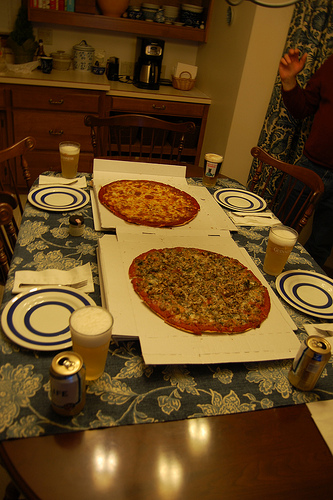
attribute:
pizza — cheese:
[93, 171, 208, 232]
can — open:
[37, 345, 98, 420]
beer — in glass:
[258, 223, 301, 278]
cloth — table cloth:
[133, 369, 210, 411]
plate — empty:
[215, 183, 273, 228]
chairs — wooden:
[4, 119, 330, 245]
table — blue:
[3, 138, 332, 419]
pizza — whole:
[129, 247, 271, 334]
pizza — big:
[125, 244, 275, 339]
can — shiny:
[49, 351, 93, 420]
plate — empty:
[29, 184, 90, 210]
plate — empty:
[213, 187, 265, 209]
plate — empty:
[274, 269, 332, 319]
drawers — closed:
[16, 84, 102, 175]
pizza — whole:
[86, 145, 233, 244]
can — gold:
[48, 346, 94, 427]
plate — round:
[210, 181, 267, 217]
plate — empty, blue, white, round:
[0, 282, 99, 354]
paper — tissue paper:
[174, 62, 197, 80]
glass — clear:
[62, 302, 118, 381]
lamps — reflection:
[82, 426, 214, 487]